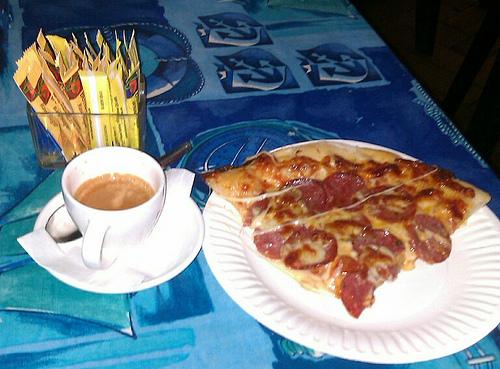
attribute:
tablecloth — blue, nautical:
[0, 2, 498, 367]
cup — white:
[60, 147, 162, 267]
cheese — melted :
[410, 174, 459, 224]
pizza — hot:
[208, 140, 485, 327]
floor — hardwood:
[359, 0, 499, 169]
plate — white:
[328, 279, 495, 366]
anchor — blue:
[309, 48, 369, 83]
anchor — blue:
[228, 54, 287, 91]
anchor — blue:
[210, 15, 262, 47]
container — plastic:
[25, 78, 150, 168]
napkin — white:
[55, 159, 172, 284]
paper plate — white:
[203, 247, 388, 363]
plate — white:
[203, 139, 498, 364]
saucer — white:
[30, 185, 206, 294]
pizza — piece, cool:
[191, 134, 485, 315]